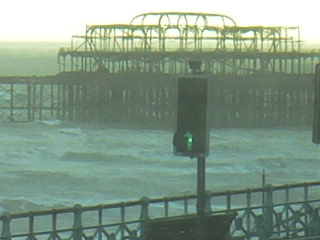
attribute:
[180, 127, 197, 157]
arrow — green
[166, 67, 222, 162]
sign — green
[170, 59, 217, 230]
traffic signal — black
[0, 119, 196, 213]
water — murky, green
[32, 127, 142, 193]
waves — choppy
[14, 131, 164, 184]
water — murky, green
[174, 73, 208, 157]
traffic sign — green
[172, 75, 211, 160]
traffic sign — black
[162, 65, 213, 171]
light — traffic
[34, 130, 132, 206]
water — blue , green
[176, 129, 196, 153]
light — green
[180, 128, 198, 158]
light — green